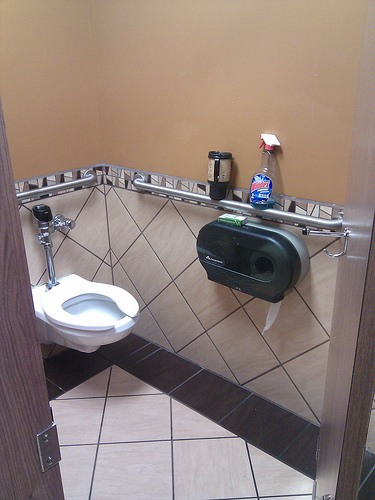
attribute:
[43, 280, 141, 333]
toilet seat — white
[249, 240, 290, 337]
toilet tissue — white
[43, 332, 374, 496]
tile — black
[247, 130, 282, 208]
windex — blue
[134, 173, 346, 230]
hand rail — stainless, steel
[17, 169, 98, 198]
hand rail — stainless, steel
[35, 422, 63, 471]
door hinge — silver, metal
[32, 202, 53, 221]
flushing device — automatic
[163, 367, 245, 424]
tile — black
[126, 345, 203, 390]
tile — black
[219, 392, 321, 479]
tile — black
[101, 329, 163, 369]
tile — black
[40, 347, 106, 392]
tile — black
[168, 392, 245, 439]
tile — white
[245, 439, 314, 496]
tile — white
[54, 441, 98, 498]
tile — white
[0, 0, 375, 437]
walls — tan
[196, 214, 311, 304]
cover — black and silver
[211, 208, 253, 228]
packet — green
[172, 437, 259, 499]
tile — white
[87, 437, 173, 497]
tile — white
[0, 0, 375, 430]
wall — tan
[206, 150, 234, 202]
cup — coffee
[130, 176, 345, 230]
rail — handicap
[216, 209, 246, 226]
carton — green, white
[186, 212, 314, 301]
holder — toilet paper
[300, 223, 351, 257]
rack — coat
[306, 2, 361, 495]
door — bathroom stall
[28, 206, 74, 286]
pipe — silver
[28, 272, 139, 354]
toilet — white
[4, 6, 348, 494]
stall — bathroom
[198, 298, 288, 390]
tile — brown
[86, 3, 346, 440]
wall — bathroom